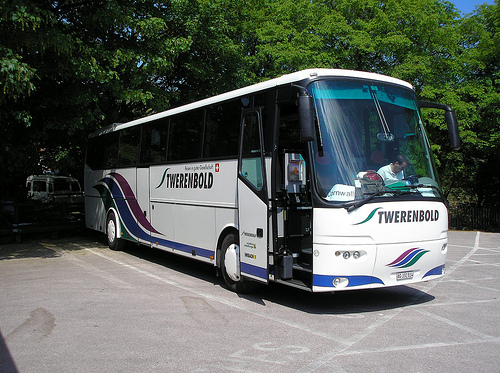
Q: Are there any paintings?
A: No, there are no paintings.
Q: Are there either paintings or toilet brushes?
A: No, there are no paintings or toilet brushes.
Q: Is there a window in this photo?
A: Yes, there are windows.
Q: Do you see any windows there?
A: Yes, there are windows.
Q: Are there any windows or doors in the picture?
A: Yes, there are windows.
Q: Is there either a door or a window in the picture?
A: Yes, there are windows.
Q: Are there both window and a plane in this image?
A: No, there are windows but no airplanes.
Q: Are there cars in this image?
A: No, there are no cars.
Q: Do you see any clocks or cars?
A: No, there are no cars or clocks.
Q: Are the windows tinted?
A: Yes, the windows are tinted.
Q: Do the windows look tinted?
A: Yes, the windows are tinted.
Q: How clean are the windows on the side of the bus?
A: The windows are tinted.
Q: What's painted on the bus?
A: The logo is painted on the bus.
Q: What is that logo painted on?
A: The logo is painted on the bus.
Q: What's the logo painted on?
A: The logo is painted on the bus.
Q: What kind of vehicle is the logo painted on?
A: The logo is painted on the bus.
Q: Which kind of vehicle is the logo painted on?
A: The logo is painted on the bus.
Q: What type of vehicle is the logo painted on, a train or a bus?
A: The logo is painted on a bus.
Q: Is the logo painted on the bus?
A: Yes, the logo is painted on the bus.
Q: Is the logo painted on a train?
A: No, the logo is painted on the bus.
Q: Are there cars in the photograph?
A: No, there are no cars.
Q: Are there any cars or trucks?
A: No, there are no cars or trucks.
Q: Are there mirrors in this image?
A: Yes, there is a mirror.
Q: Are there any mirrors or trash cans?
A: Yes, there is a mirror.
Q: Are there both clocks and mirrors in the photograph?
A: No, there is a mirror but no clocks.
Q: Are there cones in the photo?
A: No, there are no cones.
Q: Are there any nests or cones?
A: No, there are no cones or nests.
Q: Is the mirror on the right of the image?
A: Yes, the mirror is on the right of the image.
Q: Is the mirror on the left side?
A: No, the mirror is on the right of the image.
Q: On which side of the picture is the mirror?
A: The mirror is on the right of the image.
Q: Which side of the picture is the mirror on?
A: The mirror is on the right of the image.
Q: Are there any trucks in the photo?
A: No, there are no trucks.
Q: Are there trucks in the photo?
A: No, there are no trucks.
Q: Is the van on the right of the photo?
A: No, the van is on the left of the image.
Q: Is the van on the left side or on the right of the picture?
A: The van is on the left of the image.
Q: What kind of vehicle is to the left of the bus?
A: The vehicle is a van.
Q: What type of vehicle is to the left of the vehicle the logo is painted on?
A: The vehicle is a van.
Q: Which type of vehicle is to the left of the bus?
A: The vehicle is a van.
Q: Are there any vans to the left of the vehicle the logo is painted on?
A: Yes, there is a van to the left of the bus.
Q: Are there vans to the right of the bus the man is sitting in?
A: No, the van is to the left of the bus.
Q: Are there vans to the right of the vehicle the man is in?
A: No, the van is to the left of the bus.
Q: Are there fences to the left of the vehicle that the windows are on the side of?
A: No, there is a van to the left of the bus.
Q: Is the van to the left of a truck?
A: No, the van is to the left of the bus.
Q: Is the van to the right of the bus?
A: No, the van is to the left of the bus.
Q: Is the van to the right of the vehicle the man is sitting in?
A: No, the van is to the left of the bus.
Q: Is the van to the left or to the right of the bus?
A: The van is to the left of the bus.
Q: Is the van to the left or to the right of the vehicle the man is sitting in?
A: The van is to the left of the bus.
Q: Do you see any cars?
A: No, there are no cars.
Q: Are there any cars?
A: No, there are no cars.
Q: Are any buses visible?
A: Yes, there is a bus.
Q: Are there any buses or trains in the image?
A: Yes, there is a bus.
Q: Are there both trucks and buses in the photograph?
A: No, there is a bus but no trucks.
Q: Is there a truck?
A: No, there are no trucks.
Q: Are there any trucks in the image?
A: No, there are no trucks.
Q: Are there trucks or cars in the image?
A: No, there are no trucks or cars.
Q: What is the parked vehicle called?
A: The vehicle is a bus.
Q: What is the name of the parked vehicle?
A: The vehicle is a bus.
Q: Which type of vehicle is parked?
A: The vehicle is a bus.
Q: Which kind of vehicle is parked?
A: The vehicle is a bus.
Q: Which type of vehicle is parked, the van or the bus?
A: The bus is parked.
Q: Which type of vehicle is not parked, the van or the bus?
A: The van is not parked.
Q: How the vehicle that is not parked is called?
A: The vehicle is a van.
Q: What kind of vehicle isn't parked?
A: The vehicle is a van.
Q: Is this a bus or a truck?
A: This is a bus.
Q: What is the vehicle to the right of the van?
A: The vehicle is a bus.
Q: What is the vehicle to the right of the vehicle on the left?
A: The vehicle is a bus.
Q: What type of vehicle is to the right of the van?
A: The vehicle is a bus.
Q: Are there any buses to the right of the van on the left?
A: Yes, there is a bus to the right of the van.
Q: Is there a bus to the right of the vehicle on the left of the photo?
A: Yes, there is a bus to the right of the van.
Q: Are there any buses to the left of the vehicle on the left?
A: No, the bus is to the right of the van.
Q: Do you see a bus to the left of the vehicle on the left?
A: No, the bus is to the right of the van.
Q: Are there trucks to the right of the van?
A: No, there is a bus to the right of the van.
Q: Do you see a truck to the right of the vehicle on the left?
A: No, there is a bus to the right of the van.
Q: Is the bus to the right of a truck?
A: No, the bus is to the right of a van.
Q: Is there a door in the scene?
A: Yes, there is a door.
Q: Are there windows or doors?
A: Yes, there is a door.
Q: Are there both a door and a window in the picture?
A: Yes, there are both a door and a window.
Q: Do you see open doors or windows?
A: Yes, there is an open door.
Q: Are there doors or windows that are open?
A: Yes, the door is open.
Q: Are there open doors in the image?
A: Yes, there is an open door.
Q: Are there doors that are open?
A: Yes, there is a door that is open.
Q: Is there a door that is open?
A: Yes, there is a door that is open.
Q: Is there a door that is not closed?
A: Yes, there is a open door.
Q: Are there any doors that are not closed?
A: Yes, there is a open door.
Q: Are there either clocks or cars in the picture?
A: No, there are no cars or clocks.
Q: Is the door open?
A: Yes, the door is open.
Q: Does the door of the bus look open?
A: Yes, the door is open.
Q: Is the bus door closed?
A: No, the door is open.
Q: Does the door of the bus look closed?
A: No, the door is open.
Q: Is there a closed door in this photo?
A: No, there is a door but it is open.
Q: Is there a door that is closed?
A: No, there is a door but it is open.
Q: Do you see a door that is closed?
A: No, there is a door but it is open.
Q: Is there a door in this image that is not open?
A: No, there is a door but it is open.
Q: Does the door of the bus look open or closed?
A: The door is open.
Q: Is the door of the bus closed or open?
A: The door is open.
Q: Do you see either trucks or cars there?
A: No, there are no cars or trucks.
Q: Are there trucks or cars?
A: No, there are no cars or trucks.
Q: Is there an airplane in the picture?
A: No, there are no airplanes.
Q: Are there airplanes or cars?
A: No, there are no airplanes or cars.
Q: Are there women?
A: No, there are no women.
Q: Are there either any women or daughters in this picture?
A: No, there are no women or daughters.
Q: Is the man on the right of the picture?
A: Yes, the man is on the right of the image.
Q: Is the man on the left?
A: No, the man is on the right of the image.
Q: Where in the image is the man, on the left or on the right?
A: The man is on the right of the image.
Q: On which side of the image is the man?
A: The man is on the right of the image.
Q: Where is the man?
A: The man is in the bus.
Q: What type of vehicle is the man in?
A: The man is in the bus.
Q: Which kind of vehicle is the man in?
A: The man is in the bus.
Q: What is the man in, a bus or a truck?
A: The man is in a bus.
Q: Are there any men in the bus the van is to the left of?
A: Yes, there is a man in the bus.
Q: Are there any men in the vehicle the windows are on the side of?
A: Yes, there is a man in the bus.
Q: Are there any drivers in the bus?
A: No, there is a man in the bus.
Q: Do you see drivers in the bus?
A: No, there is a man in the bus.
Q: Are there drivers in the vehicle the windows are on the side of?
A: No, there is a man in the bus.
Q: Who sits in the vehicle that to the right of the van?
A: The man sits in the bus.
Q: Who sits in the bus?
A: The man sits in the bus.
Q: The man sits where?
A: The man sits in the bus.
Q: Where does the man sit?
A: The man sits in the bus.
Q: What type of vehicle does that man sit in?
A: The man sits in the bus.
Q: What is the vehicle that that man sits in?
A: The vehicle is a bus.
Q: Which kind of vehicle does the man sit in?
A: The man sits in the bus.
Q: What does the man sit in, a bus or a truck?
A: The man sits in a bus.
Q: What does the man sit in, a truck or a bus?
A: The man sits in a bus.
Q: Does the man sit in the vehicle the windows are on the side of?
A: Yes, the man sits in the bus.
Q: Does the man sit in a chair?
A: No, the man sits in the bus.